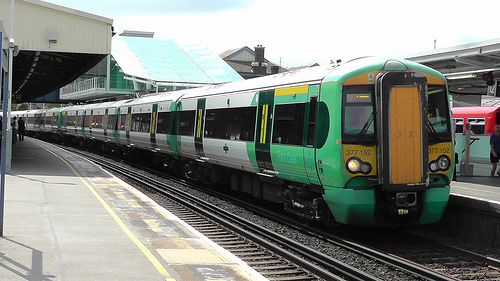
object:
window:
[424, 82, 453, 145]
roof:
[112, 34, 250, 87]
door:
[253, 88, 275, 176]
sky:
[40, 1, 500, 73]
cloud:
[44, 0, 500, 72]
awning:
[0, 0, 115, 105]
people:
[15, 115, 27, 141]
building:
[217, 40, 290, 81]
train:
[0, 54, 460, 230]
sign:
[275, 149, 298, 165]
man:
[487, 122, 500, 178]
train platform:
[0, 134, 275, 280]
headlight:
[344, 157, 363, 172]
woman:
[462, 122, 476, 135]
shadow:
[0, 235, 61, 280]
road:
[446, 174, 499, 206]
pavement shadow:
[0, 134, 120, 179]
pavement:
[1, 134, 279, 281]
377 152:
[342, 149, 372, 159]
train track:
[58, 143, 387, 280]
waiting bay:
[0, 112, 30, 142]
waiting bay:
[8, 129, 86, 172]